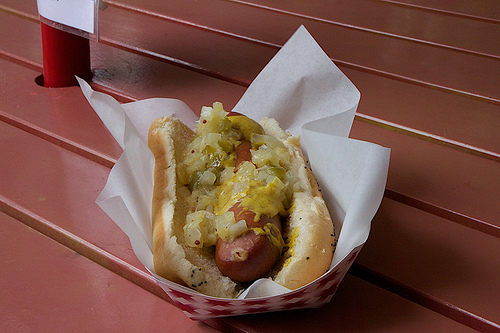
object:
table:
[0, 0, 499, 332]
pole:
[40, 0, 102, 87]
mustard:
[226, 109, 262, 134]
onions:
[214, 210, 251, 243]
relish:
[227, 144, 240, 164]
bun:
[143, 101, 335, 301]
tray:
[134, 243, 358, 323]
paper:
[74, 25, 389, 301]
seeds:
[304, 255, 312, 260]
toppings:
[213, 208, 251, 244]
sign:
[32, 0, 103, 44]